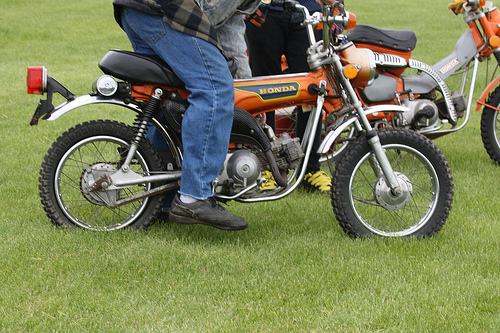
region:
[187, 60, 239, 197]
thejeans are blue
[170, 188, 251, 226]
the shoes are black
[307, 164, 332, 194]
the laces are yellow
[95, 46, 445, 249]
the bike is orange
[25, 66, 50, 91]
the tail light is red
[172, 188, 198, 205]
the socks are white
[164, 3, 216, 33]
the jamper is black and grey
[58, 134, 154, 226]
the spokes are silver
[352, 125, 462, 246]
the tirs is black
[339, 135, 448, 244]
the tire is rubber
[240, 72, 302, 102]
The motorcycle in front is honda brand.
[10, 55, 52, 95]
The rear light is red.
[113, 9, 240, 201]
A man wearing jeans is on the motorcycle.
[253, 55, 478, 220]
There are 2 motorcycles.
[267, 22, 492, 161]
Both bikes are orange.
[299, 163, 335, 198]
A shoe on a foot in the background has yellow laces.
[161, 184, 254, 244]
A black shoe on a mans foot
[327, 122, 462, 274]
The tires look new.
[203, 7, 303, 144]
A man's arm reaches down.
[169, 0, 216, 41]
The man is wearing a flannel shirt.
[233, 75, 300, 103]
honda is written on the bike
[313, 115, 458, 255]
the wheels are black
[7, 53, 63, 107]
the brake light is red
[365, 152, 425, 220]
the spokes are silver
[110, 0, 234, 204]
the person is wearing jeans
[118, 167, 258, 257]
the sneakers are black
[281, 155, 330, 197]
the shoelaces are yellow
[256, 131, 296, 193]
the hose is black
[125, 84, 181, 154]
the bike spring is black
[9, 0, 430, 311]
the bikes are on the grass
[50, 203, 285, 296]
the grass is green.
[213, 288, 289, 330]
the grass is green.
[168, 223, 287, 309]
the grass is green.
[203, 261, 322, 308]
the grass is green.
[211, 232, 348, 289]
the grass is green.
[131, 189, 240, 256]
the grass is green.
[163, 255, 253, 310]
the grass is green.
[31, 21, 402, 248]
a orange motorcycle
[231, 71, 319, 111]
writing on a motorcycle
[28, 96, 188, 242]
rear tire on a motorcycle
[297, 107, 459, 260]
front tire on a motorcycle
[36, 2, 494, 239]
two orange motorcycles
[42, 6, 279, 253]
a person on a motorcycle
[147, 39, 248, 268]
a person wearing blue jeans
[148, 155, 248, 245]
a person wearing black shoes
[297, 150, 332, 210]
a person wearing black shoes with yellow laces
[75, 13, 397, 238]
two people on motorcycles